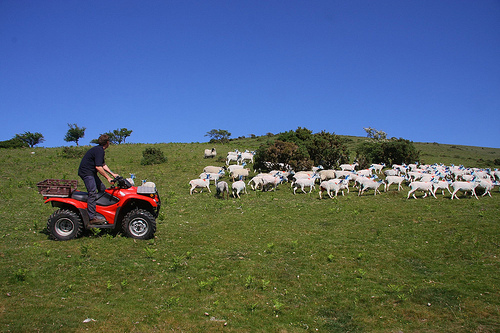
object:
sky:
[1, 0, 499, 149]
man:
[77, 134, 120, 224]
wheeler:
[35, 173, 161, 240]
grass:
[0, 134, 500, 333]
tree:
[63, 122, 86, 146]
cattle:
[189, 147, 500, 200]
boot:
[90, 216, 106, 224]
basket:
[37, 178, 78, 194]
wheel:
[45, 208, 85, 241]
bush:
[253, 126, 420, 173]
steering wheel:
[110, 176, 131, 185]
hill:
[0, 132, 499, 332]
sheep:
[318, 179, 349, 200]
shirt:
[79, 144, 105, 178]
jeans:
[78, 174, 106, 219]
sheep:
[204, 148, 217, 159]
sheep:
[449, 179, 481, 201]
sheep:
[248, 172, 284, 192]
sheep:
[189, 177, 212, 195]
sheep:
[358, 179, 385, 197]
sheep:
[405, 179, 439, 202]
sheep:
[293, 173, 321, 195]